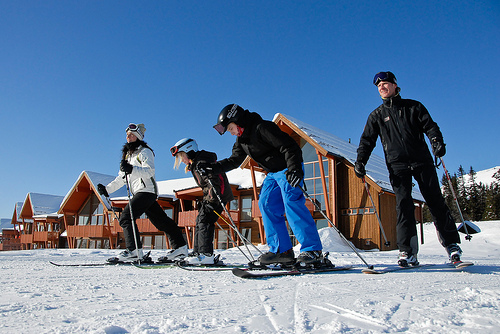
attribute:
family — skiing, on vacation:
[103, 106, 433, 260]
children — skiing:
[106, 113, 226, 267]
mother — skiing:
[210, 75, 317, 274]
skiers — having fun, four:
[114, 131, 374, 301]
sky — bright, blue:
[156, 14, 214, 31]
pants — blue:
[246, 170, 330, 249]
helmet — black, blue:
[211, 107, 239, 122]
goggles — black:
[366, 71, 392, 79]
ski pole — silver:
[188, 180, 250, 251]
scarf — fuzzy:
[117, 141, 149, 169]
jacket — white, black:
[112, 150, 158, 191]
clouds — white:
[454, 109, 463, 150]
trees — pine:
[455, 182, 494, 213]